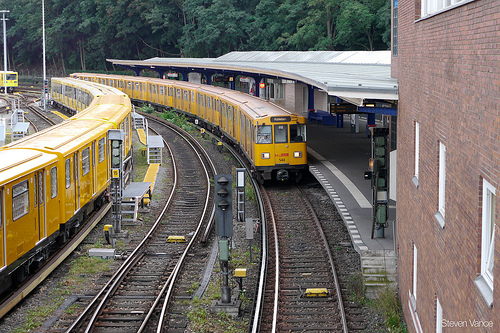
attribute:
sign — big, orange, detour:
[360, 153, 374, 185]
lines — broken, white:
[303, 164, 374, 260]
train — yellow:
[68, 70, 308, 185]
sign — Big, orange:
[190, 243, 283, 322]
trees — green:
[3, 2, 388, 49]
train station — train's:
[6, 7, 414, 295]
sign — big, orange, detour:
[362, 169, 373, 182]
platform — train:
[299, 112, 391, 257]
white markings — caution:
[308, 149, 375, 257]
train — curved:
[0, 71, 140, 323]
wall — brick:
[396, 3, 494, 330]